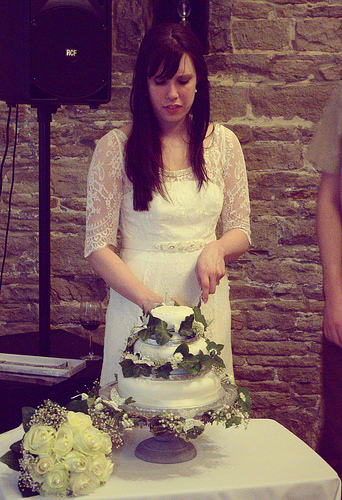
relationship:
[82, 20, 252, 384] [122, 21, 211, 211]
woman has hair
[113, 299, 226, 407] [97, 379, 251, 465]
cake sitting on stand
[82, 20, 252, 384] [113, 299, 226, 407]
woman cutting cake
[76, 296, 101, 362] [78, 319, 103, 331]
glass has drink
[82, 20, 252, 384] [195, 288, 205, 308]
woman has knife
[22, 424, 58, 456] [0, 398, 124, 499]
rose on middle of bouquet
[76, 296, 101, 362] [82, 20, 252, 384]
glass to left of woman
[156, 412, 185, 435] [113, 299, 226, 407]
flower around bottom of cake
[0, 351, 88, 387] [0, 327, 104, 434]
gift box sitting on table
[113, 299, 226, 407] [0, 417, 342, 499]
cake sitting on table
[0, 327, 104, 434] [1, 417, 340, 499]
table has table cloth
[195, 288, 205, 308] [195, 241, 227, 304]
knife held in left hand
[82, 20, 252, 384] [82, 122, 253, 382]
woman wearing bridal gown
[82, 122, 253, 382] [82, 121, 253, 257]
bridal gown has lace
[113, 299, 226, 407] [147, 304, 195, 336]
cake has layer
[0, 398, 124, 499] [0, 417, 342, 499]
bouquet sitting on table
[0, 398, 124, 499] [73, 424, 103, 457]
bouquet has rose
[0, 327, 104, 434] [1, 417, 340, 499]
table with table cloth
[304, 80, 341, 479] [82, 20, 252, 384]
person to right of woman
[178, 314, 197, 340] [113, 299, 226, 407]
leaf decorating cake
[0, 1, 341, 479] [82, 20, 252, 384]
wall behind woman